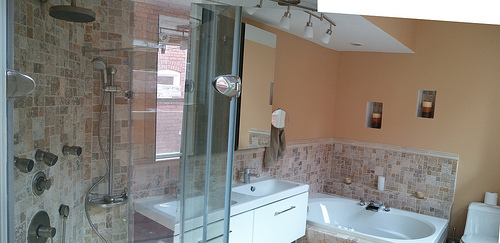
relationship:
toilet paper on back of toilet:
[481, 191, 499, 205] [461, 208, 499, 241]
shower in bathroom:
[1, 1, 224, 241] [4, 2, 497, 238]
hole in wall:
[368, 101, 383, 126] [243, 24, 496, 211]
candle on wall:
[421, 101, 432, 115] [243, 24, 496, 211]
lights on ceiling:
[239, 3, 341, 45] [247, 5, 498, 57]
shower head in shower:
[94, 53, 122, 96] [1, 1, 224, 241]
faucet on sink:
[235, 167, 259, 179] [239, 184, 297, 200]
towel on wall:
[267, 123, 290, 167] [243, 24, 496, 211]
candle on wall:
[372, 112, 380, 126] [243, 24, 496, 211]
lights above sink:
[239, 3, 341, 45] [239, 184, 297, 200]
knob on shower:
[34, 174, 55, 192] [1, 1, 224, 241]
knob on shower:
[15, 153, 32, 172] [1, 1, 224, 241]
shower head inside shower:
[94, 53, 122, 96] [1, 1, 224, 241]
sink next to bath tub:
[239, 184, 297, 200] [303, 199, 442, 242]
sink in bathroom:
[239, 184, 297, 200] [4, 2, 497, 238]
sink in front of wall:
[239, 184, 297, 200] [243, 24, 496, 211]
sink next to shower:
[239, 184, 297, 200] [1, 1, 224, 241]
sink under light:
[239, 184, 297, 200] [270, 15, 289, 28]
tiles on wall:
[240, 151, 449, 215] [243, 24, 496, 211]